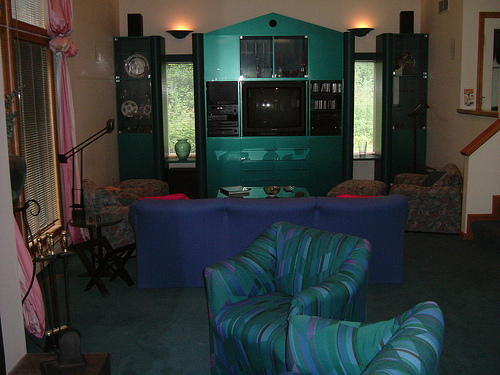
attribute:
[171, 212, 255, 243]
couch — blue, purple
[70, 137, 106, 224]
mic stand — brown, green, wooden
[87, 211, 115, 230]
table — green, wood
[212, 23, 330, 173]
entertainment center — teal, green, tall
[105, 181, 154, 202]
chairs — multicolored, camo, blue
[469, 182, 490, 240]
staircase — to the right, brown, some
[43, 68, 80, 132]
drapes — pink, open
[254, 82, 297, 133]
tv — off, small, black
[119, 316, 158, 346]
floor — carpeted, blue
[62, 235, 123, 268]
seat — colorful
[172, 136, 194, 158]
vase — green